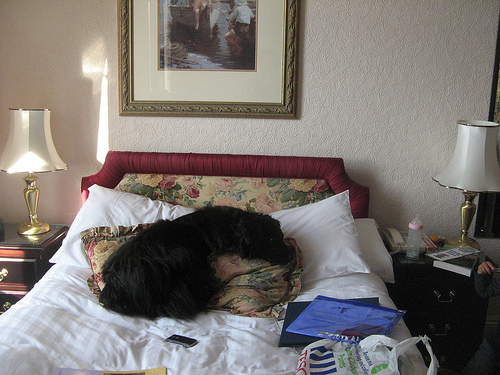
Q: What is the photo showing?
A: It is showing a bedroom.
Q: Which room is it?
A: It is a bedroom.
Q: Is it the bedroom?
A: Yes, it is the bedroom.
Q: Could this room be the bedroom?
A: Yes, it is the bedroom.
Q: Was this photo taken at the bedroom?
A: Yes, it was taken in the bedroom.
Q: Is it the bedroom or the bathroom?
A: It is the bedroom.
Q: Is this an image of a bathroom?
A: No, the picture is showing a bedroom.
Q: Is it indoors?
A: Yes, it is indoors.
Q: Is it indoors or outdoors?
A: It is indoors.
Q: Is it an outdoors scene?
A: No, it is indoors.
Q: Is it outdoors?
A: No, it is indoors.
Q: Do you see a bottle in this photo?
A: Yes, there is a bottle.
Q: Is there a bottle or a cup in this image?
A: Yes, there is a bottle.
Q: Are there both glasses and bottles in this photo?
A: No, there is a bottle but no glasses.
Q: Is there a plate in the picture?
A: No, there are no plates.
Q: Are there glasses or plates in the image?
A: No, there are no plates or glasses.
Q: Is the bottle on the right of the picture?
A: Yes, the bottle is on the right of the image.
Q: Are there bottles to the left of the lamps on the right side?
A: Yes, there is a bottle to the left of the lamps.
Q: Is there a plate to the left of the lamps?
A: No, there is a bottle to the left of the lamps.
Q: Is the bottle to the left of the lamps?
A: Yes, the bottle is to the left of the lamps.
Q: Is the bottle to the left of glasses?
A: No, the bottle is to the left of the lamps.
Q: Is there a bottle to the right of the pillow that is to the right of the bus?
A: Yes, there is a bottle to the right of the pillow.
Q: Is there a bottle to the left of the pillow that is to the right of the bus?
A: No, the bottle is to the right of the pillow.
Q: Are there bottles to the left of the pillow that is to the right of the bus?
A: No, the bottle is to the right of the pillow.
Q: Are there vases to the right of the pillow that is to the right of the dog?
A: No, there is a bottle to the right of the pillow.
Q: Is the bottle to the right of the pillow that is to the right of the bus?
A: Yes, the bottle is to the right of the pillow.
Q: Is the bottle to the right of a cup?
A: No, the bottle is to the right of the pillow.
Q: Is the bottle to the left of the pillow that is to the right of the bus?
A: No, the bottle is to the right of the pillow.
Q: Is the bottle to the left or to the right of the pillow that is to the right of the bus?
A: The bottle is to the right of the pillow.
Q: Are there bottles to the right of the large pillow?
A: Yes, there is a bottle to the right of the pillow.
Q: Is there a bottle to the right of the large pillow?
A: Yes, there is a bottle to the right of the pillow.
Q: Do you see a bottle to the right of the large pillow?
A: Yes, there is a bottle to the right of the pillow.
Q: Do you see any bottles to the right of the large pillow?
A: Yes, there is a bottle to the right of the pillow.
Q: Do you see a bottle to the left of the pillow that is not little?
A: No, the bottle is to the right of the pillow.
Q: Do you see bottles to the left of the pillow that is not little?
A: No, the bottle is to the right of the pillow.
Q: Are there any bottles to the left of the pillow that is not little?
A: No, the bottle is to the right of the pillow.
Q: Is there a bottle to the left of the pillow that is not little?
A: No, the bottle is to the right of the pillow.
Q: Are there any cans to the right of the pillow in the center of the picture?
A: No, there is a bottle to the right of the pillow.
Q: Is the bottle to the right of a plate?
A: No, the bottle is to the right of the pillow.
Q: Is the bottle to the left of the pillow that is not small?
A: No, the bottle is to the right of the pillow.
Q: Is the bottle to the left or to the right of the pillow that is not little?
A: The bottle is to the right of the pillow.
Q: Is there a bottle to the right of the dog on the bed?
A: Yes, there is a bottle to the right of the dog.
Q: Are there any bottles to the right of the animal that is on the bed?
A: Yes, there is a bottle to the right of the dog.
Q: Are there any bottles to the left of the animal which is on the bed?
A: No, the bottle is to the right of the dog.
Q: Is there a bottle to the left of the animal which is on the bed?
A: No, the bottle is to the right of the dog.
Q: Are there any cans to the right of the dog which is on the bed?
A: No, there is a bottle to the right of the dog.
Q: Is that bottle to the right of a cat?
A: No, the bottle is to the right of a dog.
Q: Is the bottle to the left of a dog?
A: No, the bottle is to the right of a dog.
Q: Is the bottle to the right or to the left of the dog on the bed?
A: The bottle is to the right of the dog.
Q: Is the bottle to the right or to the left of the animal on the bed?
A: The bottle is to the right of the dog.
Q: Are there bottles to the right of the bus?
A: Yes, there is a bottle to the right of the bus.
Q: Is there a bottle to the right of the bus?
A: Yes, there is a bottle to the right of the bus.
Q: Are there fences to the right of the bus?
A: No, there is a bottle to the right of the bus.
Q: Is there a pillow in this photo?
A: Yes, there is a pillow.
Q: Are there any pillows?
A: Yes, there is a pillow.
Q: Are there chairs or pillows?
A: Yes, there is a pillow.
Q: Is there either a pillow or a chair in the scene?
A: Yes, there is a pillow.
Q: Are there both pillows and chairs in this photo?
A: Yes, there are both a pillow and a chair.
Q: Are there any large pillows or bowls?
A: Yes, there is a large pillow.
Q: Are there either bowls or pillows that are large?
A: Yes, the pillow is large.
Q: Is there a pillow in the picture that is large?
A: Yes, there is a large pillow.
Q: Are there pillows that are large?
A: Yes, there is a pillow that is large.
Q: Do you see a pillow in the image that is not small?
A: Yes, there is a large pillow.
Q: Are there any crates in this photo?
A: No, there are no crates.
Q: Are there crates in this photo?
A: No, there are no crates.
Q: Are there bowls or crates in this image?
A: No, there are no crates or bowls.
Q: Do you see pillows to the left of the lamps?
A: Yes, there is a pillow to the left of the lamps.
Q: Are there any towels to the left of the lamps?
A: No, there is a pillow to the left of the lamps.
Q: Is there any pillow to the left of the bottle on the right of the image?
A: Yes, there is a pillow to the left of the bottle.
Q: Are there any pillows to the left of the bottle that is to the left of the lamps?
A: Yes, there is a pillow to the left of the bottle.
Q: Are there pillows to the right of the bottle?
A: No, the pillow is to the left of the bottle.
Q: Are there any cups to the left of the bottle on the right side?
A: No, there is a pillow to the left of the bottle.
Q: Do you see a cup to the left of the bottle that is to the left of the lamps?
A: No, there is a pillow to the left of the bottle.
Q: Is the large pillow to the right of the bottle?
A: No, the pillow is to the left of the bottle.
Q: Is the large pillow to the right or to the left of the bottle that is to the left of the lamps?
A: The pillow is to the left of the bottle.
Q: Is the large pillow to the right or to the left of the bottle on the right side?
A: The pillow is to the left of the bottle.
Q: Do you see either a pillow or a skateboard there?
A: Yes, there is a pillow.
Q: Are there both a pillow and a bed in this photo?
A: Yes, there are both a pillow and a bed.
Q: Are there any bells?
A: No, there are no bells.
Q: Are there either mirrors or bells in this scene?
A: No, there are no bells or mirrors.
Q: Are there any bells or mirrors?
A: No, there are no bells or mirrors.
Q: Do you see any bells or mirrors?
A: No, there are no bells or mirrors.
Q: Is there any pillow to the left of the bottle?
A: Yes, there is a pillow to the left of the bottle.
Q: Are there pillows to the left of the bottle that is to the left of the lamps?
A: Yes, there is a pillow to the left of the bottle.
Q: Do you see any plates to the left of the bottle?
A: No, there is a pillow to the left of the bottle.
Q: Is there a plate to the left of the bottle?
A: No, there is a pillow to the left of the bottle.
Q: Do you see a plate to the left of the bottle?
A: No, there is a pillow to the left of the bottle.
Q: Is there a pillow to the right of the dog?
A: Yes, there is a pillow to the right of the dog.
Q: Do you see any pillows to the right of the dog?
A: Yes, there is a pillow to the right of the dog.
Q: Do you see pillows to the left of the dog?
A: No, the pillow is to the right of the dog.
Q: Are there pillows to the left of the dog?
A: No, the pillow is to the right of the dog.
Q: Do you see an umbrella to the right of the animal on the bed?
A: No, there is a pillow to the right of the dog.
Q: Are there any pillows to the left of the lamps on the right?
A: Yes, there is a pillow to the left of the lamps.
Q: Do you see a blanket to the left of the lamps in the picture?
A: No, there is a pillow to the left of the lamps.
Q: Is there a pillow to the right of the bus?
A: Yes, there is a pillow to the right of the bus.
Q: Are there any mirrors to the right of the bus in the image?
A: No, there is a pillow to the right of the bus.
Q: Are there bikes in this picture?
A: No, there are no bikes.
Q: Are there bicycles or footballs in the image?
A: No, there are no bicycles or footballs.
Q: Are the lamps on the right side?
A: Yes, the lamps are on the right of the image.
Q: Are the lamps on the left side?
A: No, the lamps are on the right of the image.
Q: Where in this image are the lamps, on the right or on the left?
A: The lamps are on the right of the image.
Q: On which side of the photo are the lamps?
A: The lamps are on the right of the image.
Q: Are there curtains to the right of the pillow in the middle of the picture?
A: No, there are lamps to the right of the pillow.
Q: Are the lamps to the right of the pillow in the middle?
A: Yes, the lamps are to the right of the pillow.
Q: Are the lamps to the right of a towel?
A: No, the lamps are to the right of the pillow.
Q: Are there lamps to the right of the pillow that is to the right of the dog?
A: Yes, there are lamps to the right of the pillow.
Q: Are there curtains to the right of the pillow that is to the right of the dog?
A: No, there are lamps to the right of the pillow.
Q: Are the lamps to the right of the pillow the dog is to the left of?
A: Yes, the lamps are to the right of the pillow.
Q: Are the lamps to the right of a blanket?
A: No, the lamps are to the right of the pillow.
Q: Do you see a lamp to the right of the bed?
A: Yes, there are lamps to the right of the bed.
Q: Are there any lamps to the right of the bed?
A: Yes, there are lamps to the right of the bed.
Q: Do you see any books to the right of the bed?
A: No, there are lamps to the right of the bed.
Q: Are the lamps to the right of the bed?
A: Yes, the lamps are to the right of the bed.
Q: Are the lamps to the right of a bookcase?
A: No, the lamps are to the right of the bed.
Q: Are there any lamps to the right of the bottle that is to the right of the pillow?
A: Yes, there are lamps to the right of the bottle.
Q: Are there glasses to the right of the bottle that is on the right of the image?
A: No, there are lamps to the right of the bottle.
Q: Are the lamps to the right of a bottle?
A: Yes, the lamps are to the right of a bottle.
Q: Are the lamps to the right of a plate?
A: No, the lamps are to the right of a bottle.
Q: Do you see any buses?
A: Yes, there is a bus.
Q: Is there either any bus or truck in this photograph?
A: Yes, there is a bus.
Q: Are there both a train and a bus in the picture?
A: No, there is a bus but no trains.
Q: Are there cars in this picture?
A: No, there are no cars.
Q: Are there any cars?
A: No, there are no cars.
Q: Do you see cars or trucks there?
A: No, there are no cars or trucks.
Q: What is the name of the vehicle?
A: The vehicle is a bus.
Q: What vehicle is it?
A: The vehicle is a bus.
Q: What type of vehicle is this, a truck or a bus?
A: This is a bus.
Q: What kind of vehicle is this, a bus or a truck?
A: This is a bus.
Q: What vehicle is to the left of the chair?
A: The vehicle is a bus.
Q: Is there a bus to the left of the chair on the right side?
A: Yes, there is a bus to the left of the chair.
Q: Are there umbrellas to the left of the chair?
A: No, there is a bus to the left of the chair.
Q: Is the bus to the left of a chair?
A: Yes, the bus is to the left of a chair.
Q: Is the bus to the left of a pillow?
A: Yes, the bus is to the left of a pillow.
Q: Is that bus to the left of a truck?
A: No, the bus is to the left of a pillow.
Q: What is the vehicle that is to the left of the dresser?
A: The vehicle is a bus.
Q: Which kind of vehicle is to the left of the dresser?
A: The vehicle is a bus.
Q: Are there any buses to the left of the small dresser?
A: Yes, there is a bus to the left of the dresser.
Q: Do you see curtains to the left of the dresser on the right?
A: No, there is a bus to the left of the dresser.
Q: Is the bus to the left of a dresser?
A: Yes, the bus is to the left of a dresser.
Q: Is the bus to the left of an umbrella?
A: No, the bus is to the left of a dresser.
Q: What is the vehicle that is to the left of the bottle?
A: The vehicle is a bus.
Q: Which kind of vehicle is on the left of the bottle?
A: The vehicle is a bus.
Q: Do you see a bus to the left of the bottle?
A: Yes, there is a bus to the left of the bottle.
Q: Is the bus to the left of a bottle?
A: Yes, the bus is to the left of a bottle.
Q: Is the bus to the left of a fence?
A: No, the bus is to the left of a bottle.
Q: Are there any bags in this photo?
A: Yes, there is a bag.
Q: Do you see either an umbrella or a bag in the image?
A: Yes, there is a bag.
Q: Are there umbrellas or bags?
A: Yes, there is a bag.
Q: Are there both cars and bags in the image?
A: No, there is a bag but no cars.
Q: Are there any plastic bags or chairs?
A: Yes, there is a plastic bag.